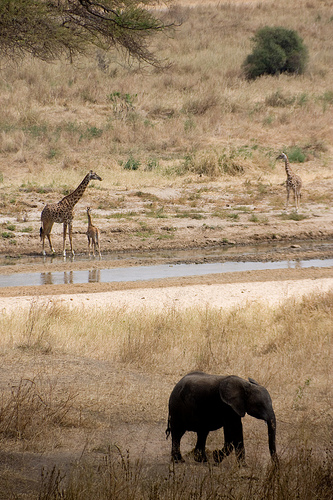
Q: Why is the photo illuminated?
A: Sunlight.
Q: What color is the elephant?
A: Gray.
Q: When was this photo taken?
A: During the day.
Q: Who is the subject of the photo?
A: The wildlife.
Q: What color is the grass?
A: Brown.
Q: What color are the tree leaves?
A: Green.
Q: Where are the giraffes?
A: On the other side of the water.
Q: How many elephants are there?
A: One.